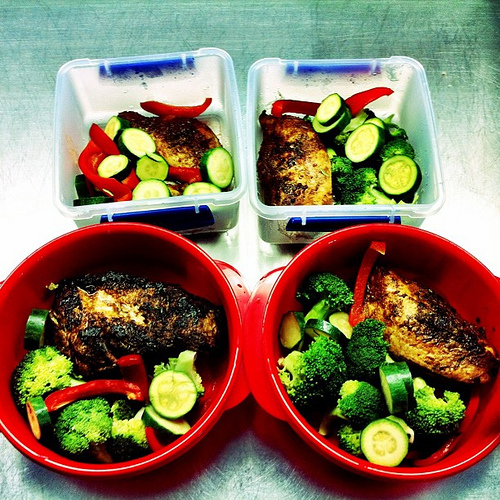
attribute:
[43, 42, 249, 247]
container — white, plastic, resealable, storage, clear, square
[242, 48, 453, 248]
container — white, resealable, storage, clear, square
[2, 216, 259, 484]
bowl — red, tabl, plastic, round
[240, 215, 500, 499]
bowl — red, table, plastic, round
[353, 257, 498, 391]
meat — grilled, barbecued, blackened, fried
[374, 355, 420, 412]
cucumber — slice, dish, sliced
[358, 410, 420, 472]
cucumber — sliced, dish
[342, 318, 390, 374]
broccoli — dish, steamed, cooked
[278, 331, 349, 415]
broccoli — dish, steamed, green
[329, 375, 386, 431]
broccoli — dish, steamed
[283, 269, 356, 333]
broccoli — dish, steamed, cooked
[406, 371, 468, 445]
broccoli — dish, steamed, cooked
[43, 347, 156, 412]
peppers — sliced, red, cooked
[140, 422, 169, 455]
peppers — sliced, red, cooked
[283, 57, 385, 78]
handle — blue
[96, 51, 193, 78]
handle — blue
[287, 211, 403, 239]
handle — blue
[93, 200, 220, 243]
handle — blue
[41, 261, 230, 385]
meat — grilled, barbecued, blackened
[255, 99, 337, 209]
meat — grilled, barbecued, brow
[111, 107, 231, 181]
meat — grilled, barbecued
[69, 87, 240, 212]
meal — portable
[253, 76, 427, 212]
meal — portable